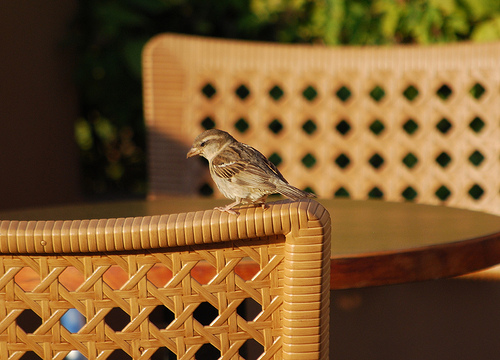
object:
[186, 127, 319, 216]
bird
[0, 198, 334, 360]
chair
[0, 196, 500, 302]
table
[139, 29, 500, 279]
chair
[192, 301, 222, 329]
holes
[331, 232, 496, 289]
edge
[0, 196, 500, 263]
surface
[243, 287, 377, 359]
leg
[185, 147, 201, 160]
beak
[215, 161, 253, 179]
part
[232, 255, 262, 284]
hole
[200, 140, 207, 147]
eye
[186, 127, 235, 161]
head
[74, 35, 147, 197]
fence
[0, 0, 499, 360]
exterior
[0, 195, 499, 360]
picture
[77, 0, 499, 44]
vegetation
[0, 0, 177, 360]
left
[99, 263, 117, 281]
spaces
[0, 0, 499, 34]
back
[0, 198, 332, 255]
weave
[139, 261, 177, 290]
design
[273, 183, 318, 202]
tail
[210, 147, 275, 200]
side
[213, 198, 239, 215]
feet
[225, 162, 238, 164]
feathers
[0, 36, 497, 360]
patio